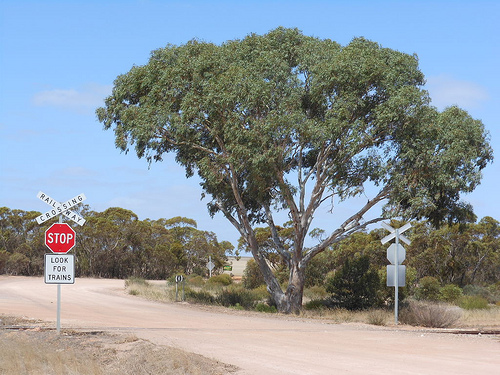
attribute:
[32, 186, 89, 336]
sign — train crossing sign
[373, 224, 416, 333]
sign — silver, railroad crossing sign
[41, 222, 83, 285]
sign — stop sign, train crossing sign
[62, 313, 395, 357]
road — unpaved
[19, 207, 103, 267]
sign — red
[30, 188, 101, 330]
railway — white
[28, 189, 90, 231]
sign — white, railway crossing sign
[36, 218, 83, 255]
stop sign — red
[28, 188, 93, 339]
railway crossing — white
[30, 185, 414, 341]
railway crossing — white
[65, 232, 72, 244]
p — large, white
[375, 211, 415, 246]
sign — grey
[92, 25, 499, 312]
tree — big, large, leafy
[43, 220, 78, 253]
stop sign — red, white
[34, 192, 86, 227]
sign — white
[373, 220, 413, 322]
sign — grey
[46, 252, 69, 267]
look — black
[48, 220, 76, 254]
stop sign — red, white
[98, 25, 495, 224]
leafy — green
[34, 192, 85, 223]
sign — railroad crossing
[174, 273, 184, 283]
sign — a railway sign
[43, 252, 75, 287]
sign — white, black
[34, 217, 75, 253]
sign — octagonal, red, white, a stop sign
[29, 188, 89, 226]
sign — white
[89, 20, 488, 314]
trees — deciduous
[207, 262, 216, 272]
sign — diamond, grey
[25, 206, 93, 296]
sign — stop sign, red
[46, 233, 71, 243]
letters — white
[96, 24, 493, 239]
foliage — green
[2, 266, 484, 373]
road — brown